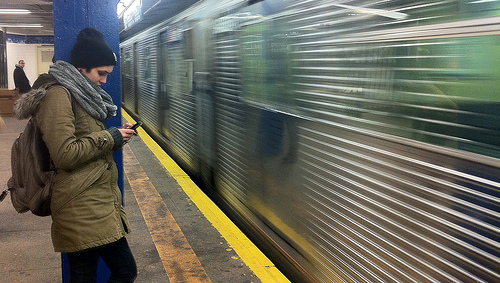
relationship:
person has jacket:
[13, 31, 138, 282] [19, 69, 132, 256]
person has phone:
[13, 31, 138, 282] [124, 116, 143, 136]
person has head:
[13, 31, 138, 282] [68, 28, 116, 96]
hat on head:
[70, 27, 116, 65] [68, 28, 116, 96]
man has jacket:
[14, 60, 32, 97] [14, 66, 33, 91]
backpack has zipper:
[11, 120, 53, 220] [15, 136, 22, 189]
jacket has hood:
[19, 69, 132, 256] [15, 74, 61, 115]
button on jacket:
[105, 138, 108, 142] [19, 69, 132, 256]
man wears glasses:
[14, 60, 32, 97] [21, 63, 26, 65]